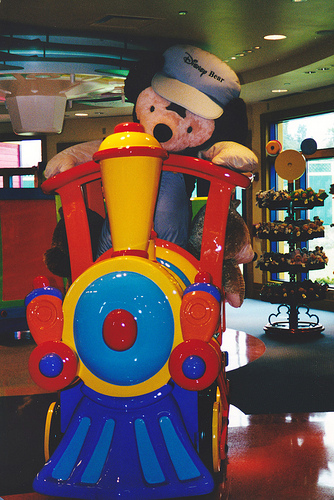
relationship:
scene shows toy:
[1, 3, 333, 498] [43, 49, 249, 277]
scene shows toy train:
[1, 3, 333, 498] [26, 124, 246, 500]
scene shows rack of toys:
[1, 3, 333, 498] [252, 191, 333, 347]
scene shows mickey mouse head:
[1, 3, 333, 498] [265, 137, 318, 181]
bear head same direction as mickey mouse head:
[227, 212, 258, 269] [265, 137, 318, 181]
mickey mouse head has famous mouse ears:
[265, 137, 318, 181] [266, 139, 318, 153]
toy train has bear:
[26, 124, 246, 500] [190, 200, 252, 309]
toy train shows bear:
[26, 124, 246, 500] [190, 200, 252, 309]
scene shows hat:
[1, 3, 333, 498] [156, 48, 245, 121]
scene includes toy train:
[1, 3, 333, 498] [26, 124, 246, 500]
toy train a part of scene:
[26, 124, 246, 500] [1, 3, 333, 498]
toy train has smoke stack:
[26, 124, 246, 500] [101, 119, 154, 260]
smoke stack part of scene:
[101, 119, 154, 260] [1, 3, 333, 498]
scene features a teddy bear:
[1, 3, 333, 498] [37, 207, 110, 278]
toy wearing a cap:
[43, 49, 249, 277] [156, 48, 245, 121]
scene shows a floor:
[1, 3, 333, 498] [234, 419, 328, 491]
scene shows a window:
[1, 3, 333, 498] [259, 113, 332, 293]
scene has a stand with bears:
[1, 3, 333, 498] [252, 191, 333, 347]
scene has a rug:
[1, 3, 333, 498] [229, 360, 332, 416]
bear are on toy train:
[190, 200, 252, 309] [26, 124, 246, 500]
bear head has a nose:
[227, 212, 258, 269] [253, 250, 258, 262]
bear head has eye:
[227, 212, 258, 269] [242, 241, 253, 250]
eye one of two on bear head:
[242, 241, 253, 250] [227, 212, 258, 269]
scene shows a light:
[1, 3, 333, 498] [266, 34, 288, 42]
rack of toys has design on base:
[252, 191, 333, 347] [266, 306, 320, 333]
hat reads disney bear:
[156, 48, 245, 121] [181, 48, 230, 87]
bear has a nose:
[190, 200, 252, 309] [253, 250, 258, 262]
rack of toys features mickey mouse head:
[252, 191, 333, 347] [265, 137, 318, 181]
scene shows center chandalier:
[1, 3, 333, 498] [1, 74, 115, 144]